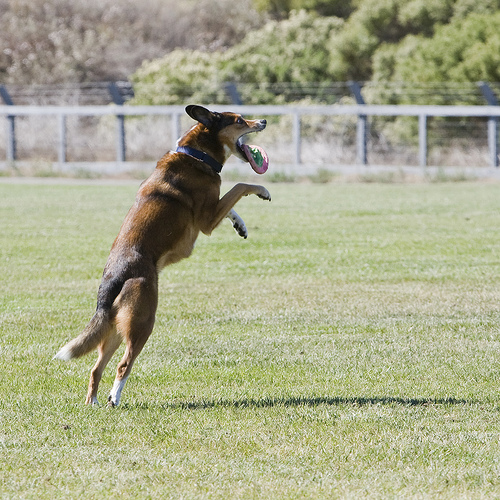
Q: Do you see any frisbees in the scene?
A: Yes, there is a frisbee.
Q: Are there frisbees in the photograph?
A: Yes, there is a frisbee.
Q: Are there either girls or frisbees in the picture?
A: Yes, there is a frisbee.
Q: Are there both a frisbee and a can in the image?
A: No, there is a frisbee but no cans.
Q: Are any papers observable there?
A: No, there are no papers.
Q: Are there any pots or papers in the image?
A: No, there are no papers or pots.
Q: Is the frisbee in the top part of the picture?
A: Yes, the frisbee is in the top of the image.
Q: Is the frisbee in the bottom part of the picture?
A: No, the frisbee is in the top of the image.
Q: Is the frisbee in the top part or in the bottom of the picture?
A: The frisbee is in the top of the image.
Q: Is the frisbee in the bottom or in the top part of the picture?
A: The frisbee is in the top of the image.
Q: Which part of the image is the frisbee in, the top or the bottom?
A: The frisbee is in the top of the image.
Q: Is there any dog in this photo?
A: Yes, there is a dog.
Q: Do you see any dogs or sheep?
A: Yes, there is a dog.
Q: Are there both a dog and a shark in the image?
A: No, there is a dog but no sharks.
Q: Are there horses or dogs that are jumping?
A: Yes, the dog is jumping.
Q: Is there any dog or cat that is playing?
A: Yes, the dog is playing.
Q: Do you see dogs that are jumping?
A: Yes, there is a dog that is jumping.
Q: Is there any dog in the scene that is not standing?
A: Yes, there is a dog that is jumping.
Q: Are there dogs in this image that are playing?
A: Yes, there is a dog that is playing.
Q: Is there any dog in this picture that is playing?
A: Yes, there is a dog that is playing.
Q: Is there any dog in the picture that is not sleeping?
A: Yes, there is a dog that is playing.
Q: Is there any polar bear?
A: No, there are no polar bears.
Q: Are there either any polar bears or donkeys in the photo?
A: No, there are no polar bears or donkeys.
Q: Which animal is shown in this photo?
A: The animal is a dog.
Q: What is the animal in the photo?
A: The animal is a dog.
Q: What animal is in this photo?
A: The animal is a dog.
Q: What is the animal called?
A: The animal is a dog.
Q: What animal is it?
A: The animal is a dog.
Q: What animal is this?
A: This is a dog.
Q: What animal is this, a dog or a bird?
A: This is a dog.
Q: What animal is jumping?
A: The animal is a dog.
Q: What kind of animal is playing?
A: The animal is a dog.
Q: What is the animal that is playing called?
A: The animal is a dog.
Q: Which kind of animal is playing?
A: The animal is a dog.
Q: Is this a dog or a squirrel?
A: This is a dog.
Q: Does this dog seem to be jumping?
A: Yes, the dog is jumping.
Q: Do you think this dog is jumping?
A: Yes, the dog is jumping.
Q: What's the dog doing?
A: The dog is jumping.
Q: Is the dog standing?
A: No, the dog is jumping.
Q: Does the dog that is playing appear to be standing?
A: No, the dog is jumping.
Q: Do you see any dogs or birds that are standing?
A: No, there is a dog but it is jumping.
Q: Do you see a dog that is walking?
A: No, there is a dog but it is jumping.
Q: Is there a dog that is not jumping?
A: No, there is a dog but it is jumping.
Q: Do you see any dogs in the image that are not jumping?
A: No, there is a dog but it is jumping.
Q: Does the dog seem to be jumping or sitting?
A: The dog is jumping.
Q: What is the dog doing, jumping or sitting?
A: The dog is jumping.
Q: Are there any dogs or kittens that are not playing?
A: No, there is a dog but it is playing.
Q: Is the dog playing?
A: Yes, the dog is playing.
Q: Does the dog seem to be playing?
A: Yes, the dog is playing.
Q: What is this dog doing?
A: The dog is playing.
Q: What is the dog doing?
A: The dog is playing.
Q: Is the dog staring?
A: No, the dog is playing.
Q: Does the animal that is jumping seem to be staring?
A: No, the dog is playing.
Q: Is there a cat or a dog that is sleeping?
A: No, there is a dog but it is playing.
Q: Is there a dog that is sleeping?
A: No, there is a dog but it is playing.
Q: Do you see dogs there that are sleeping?
A: No, there is a dog but it is playing.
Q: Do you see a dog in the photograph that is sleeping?
A: No, there is a dog but it is playing.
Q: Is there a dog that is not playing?
A: No, there is a dog but it is playing.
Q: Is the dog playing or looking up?
A: The dog is playing.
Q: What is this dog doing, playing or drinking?
A: The dog is playing.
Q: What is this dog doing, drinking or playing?
A: The dog is playing.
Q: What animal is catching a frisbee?
A: The dog is catching a frisbee.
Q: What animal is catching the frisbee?
A: The dog is catching a frisbee.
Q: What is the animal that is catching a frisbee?
A: The animal is a dog.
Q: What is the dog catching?
A: The dog is catching a frisbee.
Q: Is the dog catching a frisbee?
A: Yes, the dog is catching a frisbee.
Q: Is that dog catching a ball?
A: No, the dog is catching a frisbee.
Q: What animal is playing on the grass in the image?
A: The dog is playing on the grass.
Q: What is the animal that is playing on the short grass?
A: The animal is a dog.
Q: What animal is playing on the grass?
A: The animal is a dog.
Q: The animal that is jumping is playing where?
A: The dog is playing on the grass.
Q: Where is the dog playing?
A: The dog is playing on the grass.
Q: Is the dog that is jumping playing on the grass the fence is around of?
A: Yes, the dog is playing on the grass.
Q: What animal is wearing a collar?
A: The dog is wearing a collar.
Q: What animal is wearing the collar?
A: The dog is wearing a collar.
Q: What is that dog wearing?
A: The dog is wearing a collar.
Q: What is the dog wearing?
A: The dog is wearing a collar.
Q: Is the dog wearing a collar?
A: Yes, the dog is wearing a collar.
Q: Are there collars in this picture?
A: Yes, there is a collar.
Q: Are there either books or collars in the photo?
A: Yes, there is a collar.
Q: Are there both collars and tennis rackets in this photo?
A: No, there is a collar but no rackets.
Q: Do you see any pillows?
A: No, there are no pillows.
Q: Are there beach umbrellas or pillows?
A: No, there are no pillows or beach umbrellas.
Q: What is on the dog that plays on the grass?
A: The collar is on the dog.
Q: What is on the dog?
A: The collar is on the dog.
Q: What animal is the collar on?
A: The collar is on the dog.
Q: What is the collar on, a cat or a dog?
A: The collar is on a dog.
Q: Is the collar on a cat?
A: No, the collar is on the dog.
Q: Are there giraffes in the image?
A: No, there are no giraffes.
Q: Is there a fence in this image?
A: Yes, there is a fence.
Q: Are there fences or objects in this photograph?
A: Yes, there is a fence.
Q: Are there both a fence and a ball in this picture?
A: No, there is a fence but no balls.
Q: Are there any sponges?
A: No, there are no sponges.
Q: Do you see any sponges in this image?
A: No, there are no sponges.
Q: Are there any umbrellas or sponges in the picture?
A: No, there are no sponges or umbrellas.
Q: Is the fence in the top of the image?
A: Yes, the fence is in the top of the image.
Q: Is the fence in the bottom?
A: No, the fence is in the top of the image.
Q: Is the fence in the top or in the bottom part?
A: The fence is in the top of the image.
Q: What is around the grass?
A: The fence is around the grass.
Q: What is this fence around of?
A: The fence is around the grass.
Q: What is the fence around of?
A: The fence is around the grass.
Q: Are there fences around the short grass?
A: Yes, there is a fence around the grass.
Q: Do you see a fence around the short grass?
A: Yes, there is a fence around the grass.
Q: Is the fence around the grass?
A: Yes, the fence is around the grass.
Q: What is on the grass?
A: The fence is on the grass.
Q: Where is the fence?
A: The fence is on the grass.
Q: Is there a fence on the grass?
A: Yes, there is a fence on the grass.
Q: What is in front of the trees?
A: The fence is in front of the trees.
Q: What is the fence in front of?
A: The fence is in front of the trees.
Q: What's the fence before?
A: The fence is in front of the trees.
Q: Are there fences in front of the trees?
A: Yes, there is a fence in front of the trees.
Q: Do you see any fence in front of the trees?
A: Yes, there is a fence in front of the trees.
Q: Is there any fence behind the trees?
A: No, the fence is in front of the trees.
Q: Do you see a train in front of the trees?
A: No, there is a fence in front of the trees.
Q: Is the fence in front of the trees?
A: Yes, the fence is in front of the trees.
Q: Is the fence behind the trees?
A: No, the fence is in front of the trees.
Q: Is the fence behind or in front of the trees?
A: The fence is in front of the trees.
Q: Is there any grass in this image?
A: Yes, there is grass.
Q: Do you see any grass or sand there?
A: Yes, there is grass.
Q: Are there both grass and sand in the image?
A: No, there is grass but no sand.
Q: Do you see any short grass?
A: Yes, there is short grass.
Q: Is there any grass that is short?
A: Yes, there is grass that is short.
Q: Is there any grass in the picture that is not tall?
A: Yes, there is short grass.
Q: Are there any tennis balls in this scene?
A: No, there are no tennis balls.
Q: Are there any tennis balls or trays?
A: No, there are no tennis balls or trays.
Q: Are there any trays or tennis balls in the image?
A: No, there are no tennis balls or trays.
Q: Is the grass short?
A: Yes, the grass is short.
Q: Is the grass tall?
A: No, the grass is short.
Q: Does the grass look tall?
A: No, the grass is short.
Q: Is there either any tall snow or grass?
A: No, there is grass but it is short.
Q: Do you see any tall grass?
A: No, there is grass but it is short.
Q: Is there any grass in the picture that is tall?
A: No, there is grass but it is short.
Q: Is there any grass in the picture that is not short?
A: No, there is grass but it is short.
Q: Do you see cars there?
A: No, there are no cars.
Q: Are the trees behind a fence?
A: Yes, the trees are behind a fence.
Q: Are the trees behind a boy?
A: No, the trees are behind a fence.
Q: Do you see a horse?
A: No, there are no horses.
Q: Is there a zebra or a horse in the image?
A: No, there are no horses or zebras.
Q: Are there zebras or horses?
A: No, there are no horses or zebras.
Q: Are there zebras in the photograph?
A: No, there are no zebras.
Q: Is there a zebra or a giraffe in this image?
A: No, there are no zebras or giraffes.